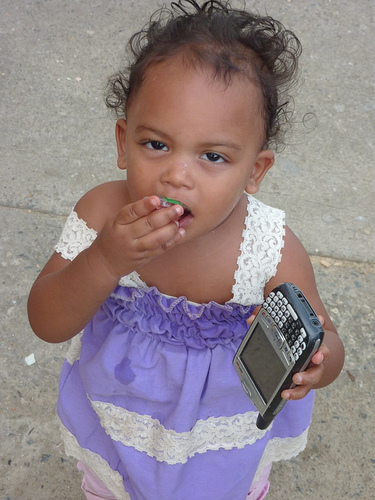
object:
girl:
[27, 1, 345, 500]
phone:
[231, 282, 324, 429]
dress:
[48, 187, 320, 499]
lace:
[225, 191, 286, 306]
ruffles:
[155, 295, 254, 321]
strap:
[53, 207, 148, 289]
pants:
[70, 458, 274, 499]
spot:
[113, 358, 137, 384]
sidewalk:
[3, 2, 372, 500]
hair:
[102, 0, 321, 155]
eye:
[198, 148, 234, 165]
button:
[286, 301, 299, 322]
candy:
[160, 196, 183, 210]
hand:
[244, 297, 327, 410]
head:
[106, 8, 300, 249]